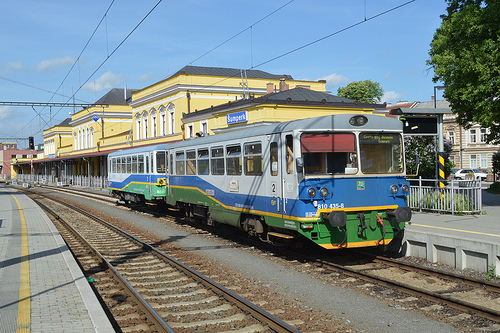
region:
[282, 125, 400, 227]
A light passenger train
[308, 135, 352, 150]
A blind on the window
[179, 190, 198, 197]
The green on the train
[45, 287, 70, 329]
A cobal stone surface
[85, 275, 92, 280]
A piece of green trash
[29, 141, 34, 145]
A red light above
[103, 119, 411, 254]
a two car train pulling in to the station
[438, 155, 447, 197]
a black and yellow striped pole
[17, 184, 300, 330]
a long brown rail road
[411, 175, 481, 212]
a small metal fence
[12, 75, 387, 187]
a long yellow row of buildings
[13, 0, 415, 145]
long spanning train cables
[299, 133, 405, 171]
front windshield of a train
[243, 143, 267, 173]
side windows of a train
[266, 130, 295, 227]
side door of a train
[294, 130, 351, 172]
window of a train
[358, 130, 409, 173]
window of a train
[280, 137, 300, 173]
window of a train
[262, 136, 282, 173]
window of a train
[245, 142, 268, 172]
window of a train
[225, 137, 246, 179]
window of a train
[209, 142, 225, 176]
window of a train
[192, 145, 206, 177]
window of a train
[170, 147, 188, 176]
window of a train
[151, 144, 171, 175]
window of a train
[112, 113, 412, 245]
A blue, green, and white train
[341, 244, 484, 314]
The train is on steel tracks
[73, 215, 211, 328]
There are rocks all over the tracks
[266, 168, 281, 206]
Number 2 on the side of the train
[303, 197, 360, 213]
Number 810 435-8 on the front of the train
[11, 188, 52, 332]
Yellow line on the passenger platform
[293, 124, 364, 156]
Red shade in the windshield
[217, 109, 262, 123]
Blue and white sign on the building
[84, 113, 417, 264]
There are two train cars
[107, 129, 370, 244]
silver blue and green light rail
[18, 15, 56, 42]
white clouds in blue sky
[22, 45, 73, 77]
white clouds in blue sky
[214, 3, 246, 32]
white clouds in blue sky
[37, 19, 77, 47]
white clouds in blue sky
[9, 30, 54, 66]
white clouds in blue sky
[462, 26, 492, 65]
green leaves on the tree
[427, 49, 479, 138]
green leaves on the tree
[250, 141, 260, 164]
a window on the train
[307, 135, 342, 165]
a window on the train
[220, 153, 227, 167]
a window on the train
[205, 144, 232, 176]
a window on the train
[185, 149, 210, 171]
a window on the train